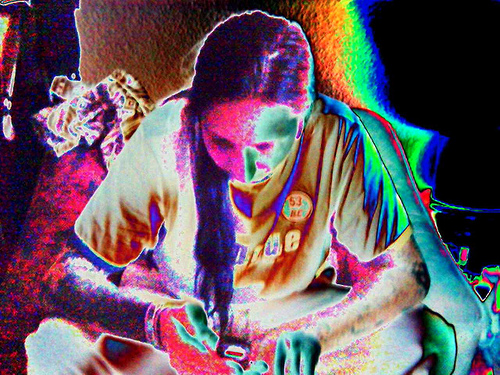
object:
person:
[22, 6, 437, 375]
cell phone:
[216, 336, 252, 364]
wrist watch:
[145, 298, 175, 352]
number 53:
[290, 195, 302, 206]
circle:
[282, 190, 313, 222]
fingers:
[303, 350, 320, 375]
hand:
[150, 295, 270, 375]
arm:
[40, 131, 159, 350]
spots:
[43, 273, 151, 345]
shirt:
[73, 88, 410, 309]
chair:
[48, 103, 489, 375]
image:
[0, 0, 499, 375]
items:
[34, 74, 156, 172]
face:
[201, 98, 298, 184]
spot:
[209, 100, 257, 137]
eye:
[254, 141, 272, 151]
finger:
[288, 338, 301, 375]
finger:
[273, 340, 287, 375]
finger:
[185, 305, 220, 342]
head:
[188, 9, 321, 189]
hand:
[271, 326, 325, 375]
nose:
[234, 148, 257, 184]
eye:
[211, 133, 236, 151]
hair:
[179, 11, 313, 334]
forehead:
[205, 100, 298, 141]